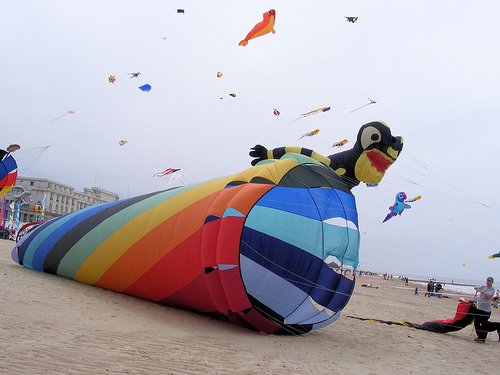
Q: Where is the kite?
A: In the sky.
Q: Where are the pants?
A: On the man.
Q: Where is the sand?
A: On the ground.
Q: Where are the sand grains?
A: On the ground.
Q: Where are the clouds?
A: In the sky.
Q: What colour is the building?
A: Gray.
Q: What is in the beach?
A: Sand.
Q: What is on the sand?
A: Kite.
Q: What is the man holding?
A: Kite.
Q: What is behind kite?
A: Building.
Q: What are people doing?
A: Watching.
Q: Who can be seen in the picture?
A: People.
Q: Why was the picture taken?
A: To capture the kite.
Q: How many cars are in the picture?
A: None.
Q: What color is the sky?
A: Blue.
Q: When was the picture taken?
A: During the day.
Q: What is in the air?
A: Kites.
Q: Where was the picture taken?
A: On a beach.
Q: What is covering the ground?
A: Sand.